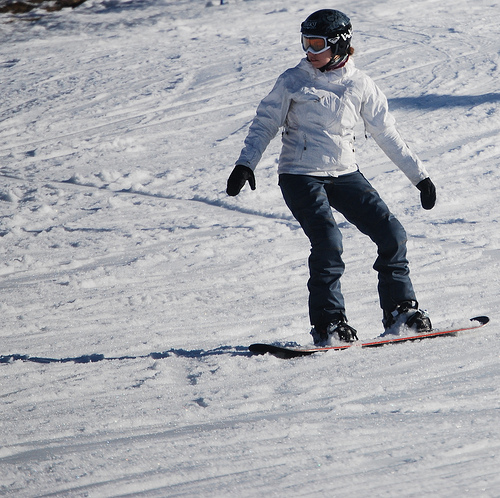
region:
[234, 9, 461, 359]
a person with snow board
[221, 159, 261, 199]
a person wearing black color gloves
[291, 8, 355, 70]
a woman wearing helmet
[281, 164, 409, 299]
a person wearing black color pant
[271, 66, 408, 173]
a person wearing white color jacket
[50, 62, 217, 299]
a place full of snow board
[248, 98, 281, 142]
elbow of the person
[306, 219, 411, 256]
knee of the person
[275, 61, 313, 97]
shoulder of the person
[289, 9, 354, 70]
head of the person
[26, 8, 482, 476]
A person is up in the mountains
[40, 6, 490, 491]
A person is it a ski resort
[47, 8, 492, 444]
A person is doing some snowboarding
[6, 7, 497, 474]
A person is casting a shadow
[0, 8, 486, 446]
A person is wearing a hat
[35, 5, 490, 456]
A person is wearing a white coat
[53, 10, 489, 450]
A person is wearing warm gloves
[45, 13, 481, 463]
A person is wearing ski goggles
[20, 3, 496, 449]
A person is wearing warm pants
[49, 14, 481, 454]
A person is enjoying the day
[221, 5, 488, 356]
snowboard coasting along in the snow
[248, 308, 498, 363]
snowboarder's board is red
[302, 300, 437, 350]
snowboard wears black boots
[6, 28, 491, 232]
the tracks of many skis and snowboards in the snow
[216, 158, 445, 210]
snowboard is wearing black gloves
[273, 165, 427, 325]
the snowboard wears black ski pants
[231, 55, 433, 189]
snowboarder is wearing a white ski jacket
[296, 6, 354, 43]
snowboarder is wearing a helmet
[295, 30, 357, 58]
snowboarder is wearing goggles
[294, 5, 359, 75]
snowboarder is watching the way ahead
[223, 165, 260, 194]
a black snow mitten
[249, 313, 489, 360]
a snow board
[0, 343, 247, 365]
the woman's shadow on the snow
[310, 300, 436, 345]
black snow books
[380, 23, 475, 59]
tracks on the snow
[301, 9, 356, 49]
a black safety helmet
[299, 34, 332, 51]
white framed goggles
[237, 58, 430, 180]
a white snow jacket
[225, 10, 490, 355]
a woman snowboarding down a hill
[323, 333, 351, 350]
pile of snow on the board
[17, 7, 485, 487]
The person is up in the mountains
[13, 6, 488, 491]
The person is using a snowboard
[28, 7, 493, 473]
The person is at a ski resort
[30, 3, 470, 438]
The person is casting a shadow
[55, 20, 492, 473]
The person is wearing a hat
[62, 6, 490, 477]
The person is wearing warm gloves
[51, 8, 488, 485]
The person is wearing a white coat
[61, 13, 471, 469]
The person is out in the daytime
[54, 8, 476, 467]
The person is enjoying the day